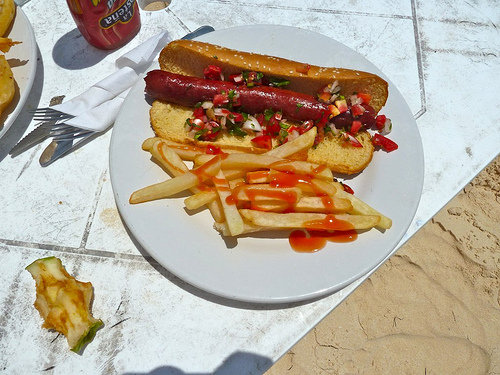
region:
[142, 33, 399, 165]
hot dog on bun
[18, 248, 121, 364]
core to half eaten apple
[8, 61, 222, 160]
forks rolled up in napkin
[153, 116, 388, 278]
french fires on plate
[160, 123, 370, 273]
red tomato ketchup on french fries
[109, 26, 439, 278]
white dinner plate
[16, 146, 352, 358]
white tile table top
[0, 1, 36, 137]
edge of white dinner plate for food on it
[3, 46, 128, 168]
butter knives wrapped in napkin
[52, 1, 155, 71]
bottom half of red bottle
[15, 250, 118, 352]
green apple core turning brown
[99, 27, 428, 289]
white plate of food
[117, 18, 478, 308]
plate with fries and hot dog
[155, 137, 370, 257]
french fries with ketchup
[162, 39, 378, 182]
hot dog with fixings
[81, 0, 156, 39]
ketchup on table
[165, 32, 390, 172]
hot dog in bun with sesame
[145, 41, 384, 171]
red hot dog in bun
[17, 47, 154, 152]
utensils wrapped in napkin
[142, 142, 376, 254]
lightly browned french fries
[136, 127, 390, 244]
the fries has ketchup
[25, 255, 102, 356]
the apple is eatan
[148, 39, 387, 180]
the hot dog is on the bun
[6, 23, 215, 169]
the fork is knife is wrapped in paper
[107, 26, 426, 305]
the plate is white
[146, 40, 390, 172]
the bun has sesame seeds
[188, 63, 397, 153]
the hotdog has pico de gallo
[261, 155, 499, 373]
the sand is brown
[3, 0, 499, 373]
the table is dirty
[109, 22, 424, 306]
the plate has food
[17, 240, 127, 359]
a green apple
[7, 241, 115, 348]
a apple core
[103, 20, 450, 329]
a white plate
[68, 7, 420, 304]
a white plate with a hotdog and french fries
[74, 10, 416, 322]
a white plate with french fries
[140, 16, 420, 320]
a white plate with a hotdog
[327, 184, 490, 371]
tan sand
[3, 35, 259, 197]
silverwear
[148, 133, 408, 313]
french fries with ketchup on them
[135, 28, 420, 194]
a red hotdog on a tan bun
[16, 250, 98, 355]
apple core is rotting